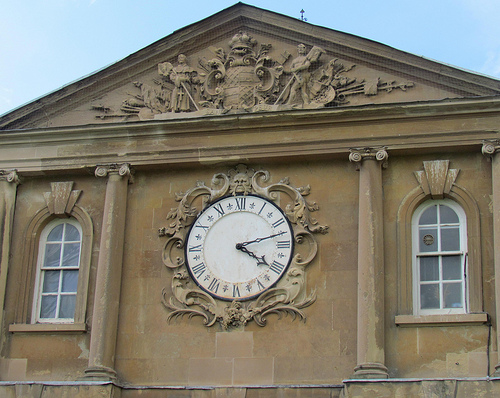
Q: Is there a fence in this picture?
A: No, there are no fences.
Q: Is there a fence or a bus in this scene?
A: No, there are no fences or buses.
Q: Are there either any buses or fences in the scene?
A: No, there are no fences or buses.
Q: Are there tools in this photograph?
A: No, there are no tools.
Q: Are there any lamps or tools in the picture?
A: No, there are no tools or lamps.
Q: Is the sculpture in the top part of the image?
A: Yes, the sculpture is in the top of the image.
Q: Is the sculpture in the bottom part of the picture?
A: No, the sculpture is in the top of the image.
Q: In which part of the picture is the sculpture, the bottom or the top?
A: The sculpture is in the top of the image.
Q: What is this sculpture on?
A: The sculpture is on the building.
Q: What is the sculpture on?
A: The sculpture is on the building.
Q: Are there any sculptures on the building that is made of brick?
A: Yes, there is a sculpture on the building.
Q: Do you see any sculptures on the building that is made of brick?
A: Yes, there is a sculpture on the building.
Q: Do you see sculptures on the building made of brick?
A: Yes, there is a sculpture on the building.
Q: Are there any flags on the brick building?
A: No, there is a sculpture on the building.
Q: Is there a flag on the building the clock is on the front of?
A: No, there is a sculpture on the building.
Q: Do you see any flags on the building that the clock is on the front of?
A: No, there is a sculpture on the building.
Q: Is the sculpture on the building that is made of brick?
A: Yes, the sculpture is on the building.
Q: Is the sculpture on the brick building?
A: Yes, the sculpture is on the building.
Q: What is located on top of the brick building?
A: The sculpture is on top of the building.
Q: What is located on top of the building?
A: The sculpture is on top of the building.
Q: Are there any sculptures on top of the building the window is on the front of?
A: Yes, there is a sculpture on top of the building.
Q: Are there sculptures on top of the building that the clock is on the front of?
A: Yes, there is a sculpture on top of the building.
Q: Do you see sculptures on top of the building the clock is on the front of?
A: Yes, there is a sculpture on top of the building.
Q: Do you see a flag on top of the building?
A: No, there is a sculpture on top of the building.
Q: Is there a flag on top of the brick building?
A: No, there is a sculpture on top of the building.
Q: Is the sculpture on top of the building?
A: Yes, the sculpture is on top of the building.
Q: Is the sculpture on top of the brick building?
A: Yes, the sculpture is on top of the building.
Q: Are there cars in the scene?
A: No, there are no cars.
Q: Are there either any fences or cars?
A: No, there are no cars or fences.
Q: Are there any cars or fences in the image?
A: No, there are no cars or fences.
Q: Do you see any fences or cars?
A: No, there are no cars or fences.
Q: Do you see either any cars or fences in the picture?
A: No, there are no cars or fences.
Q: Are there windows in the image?
A: Yes, there is a window.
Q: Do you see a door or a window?
A: Yes, there is a window.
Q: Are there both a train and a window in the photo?
A: No, there is a window but no trains.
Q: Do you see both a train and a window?
A: No, there is a window but no trains.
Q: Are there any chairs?
A: No, there are no chairs.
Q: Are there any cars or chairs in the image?
A: No, there are no chairs or cars.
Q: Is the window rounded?
A: Yes, the window is rounded.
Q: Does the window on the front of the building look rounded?
A: Yes, the window is rounded.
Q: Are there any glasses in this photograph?
A: No, there are no glasses.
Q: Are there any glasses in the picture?
A: No, there are no glasses.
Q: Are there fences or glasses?
A: No, there are no glasses or fences.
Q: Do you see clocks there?
A: Yes, there is a clock.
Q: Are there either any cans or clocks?
A: Yes, there is a clock.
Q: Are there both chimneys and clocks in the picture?
A: No, there is a clock but no chimneys.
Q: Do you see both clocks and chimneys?
A: No, there is a clock but no chimneys.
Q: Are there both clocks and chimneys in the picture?
A: No, there is a clock but no chimneys.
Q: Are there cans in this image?
A: No, there are no cans.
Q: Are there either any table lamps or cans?
A: No, there are no cans or table lamps.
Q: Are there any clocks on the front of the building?
A: Yes, there is a clock on the front of the building.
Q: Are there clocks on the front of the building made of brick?
A: Yes, there is a clock on the front of the building.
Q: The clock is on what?
A: The clock is on the building.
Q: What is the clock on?
A: The clock is on the building.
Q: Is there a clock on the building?
A: Yes, there is a clock on the building.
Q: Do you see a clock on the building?
A: Yes, there is a clock on the building.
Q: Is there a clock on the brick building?
A: Yes, there is a clock on the building.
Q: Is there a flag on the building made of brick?
A: No, there is a clock on the building.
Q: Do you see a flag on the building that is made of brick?
A: No, there is a clock on the building.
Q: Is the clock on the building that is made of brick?
A: Yes, the clock is on the building.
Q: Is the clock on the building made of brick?
A: Yes, the clock is on the building.